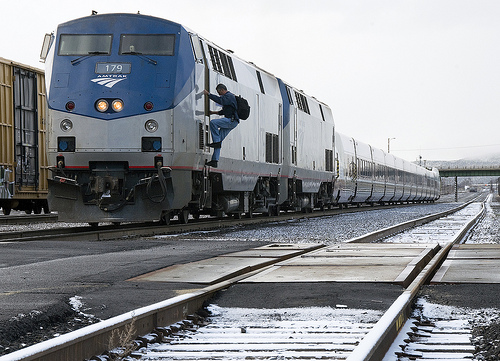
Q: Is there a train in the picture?
A: Yes, there is a train.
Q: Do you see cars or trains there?
A: Yes, there is a train.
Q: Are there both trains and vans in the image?
A: No, there is a train but no vans.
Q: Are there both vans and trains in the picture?
A: No, there is a train but no vans.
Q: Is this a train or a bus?
A: This is a train.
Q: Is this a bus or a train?
A: This is a train.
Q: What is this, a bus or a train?
A: This is a train.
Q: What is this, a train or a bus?
A: This is a train.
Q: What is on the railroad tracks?
A: The train is on the railroad tracks.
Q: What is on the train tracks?
A: The train is on the railroad tracks.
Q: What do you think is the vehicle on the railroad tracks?
A: The vehicle is a train.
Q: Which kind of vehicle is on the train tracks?
A: The vehicle is a train.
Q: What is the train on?
A: The train is on the train tracks.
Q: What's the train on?
A: The train is on the train tracks.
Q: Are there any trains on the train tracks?
A: Yes, there is a train on the train tracks.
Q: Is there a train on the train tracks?
A: Yes, there is a train on the train tracks.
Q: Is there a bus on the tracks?
A: No, there is a train on the tracks.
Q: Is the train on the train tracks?
A: Yes, the train is on the train tracks.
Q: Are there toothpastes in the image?
A: No, there are no toothpastes.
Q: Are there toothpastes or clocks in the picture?
A: No, there are no toothpastes or clocks.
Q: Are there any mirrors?
A: Yes, there is a mirror.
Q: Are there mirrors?
A: Yes, there is a mirror.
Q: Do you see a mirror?
A: Yes, there is a mirror.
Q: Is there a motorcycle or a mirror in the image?
A: Yes, there is a mirror.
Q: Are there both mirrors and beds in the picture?
A: No, there is a mirror but no beds.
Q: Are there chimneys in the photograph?
A: No, there are no chimneys.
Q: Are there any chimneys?
A: No, there are no chimneys.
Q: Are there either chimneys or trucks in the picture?
A: No, there are no chimneys or trucks.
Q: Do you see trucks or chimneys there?
A: No, there are no chimneys or trucks.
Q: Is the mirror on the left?
A: Yes, the mirror is on the left of the image.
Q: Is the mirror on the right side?
A: No, the mirror is on the left of the image.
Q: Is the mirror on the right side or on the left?
A: The mirror is on the left of the image.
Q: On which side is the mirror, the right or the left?
A: The mirror is on the left of the image.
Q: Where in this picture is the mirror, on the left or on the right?
A: The mirror is on the left of the image.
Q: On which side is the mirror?
A: The mirror is on the left of the image.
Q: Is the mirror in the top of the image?
A: Yes, the mirror is in the top of the image.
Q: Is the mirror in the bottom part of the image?
A: No, the mirror is in the top of the image.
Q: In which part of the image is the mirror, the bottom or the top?
A: The mirror is in the top of the image.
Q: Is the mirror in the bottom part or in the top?
A: The mirror is in the top of the image.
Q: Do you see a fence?
A: No, there are no fences.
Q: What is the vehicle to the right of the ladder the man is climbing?
A: The vehicle is a train car.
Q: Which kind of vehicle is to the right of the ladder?
A: The vehicle is a train car.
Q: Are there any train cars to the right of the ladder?
A: Yes, there is a train car to the right of the ladder.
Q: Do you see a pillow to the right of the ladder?
A: No, there is a train car to the right of the ladder.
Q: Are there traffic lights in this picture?
A: No, there are no traffic lights.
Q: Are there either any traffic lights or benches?
A: No, there are no traffic lights or benches.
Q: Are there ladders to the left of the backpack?
A: Yes, there is a ladder to the left of the backpack.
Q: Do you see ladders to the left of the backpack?
A: Yes, there is a ladder to the left of the backpack.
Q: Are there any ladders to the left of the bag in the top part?
A: Yes, there is a ladder to the left of the backpack.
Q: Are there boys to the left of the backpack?
A: No, there is a ladder to the left of the backpack.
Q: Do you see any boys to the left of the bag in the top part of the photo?
A: No, there is a ladder to the left of the backpack.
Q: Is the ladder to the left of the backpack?
A: Yes, the ladder is to the left of the backpack.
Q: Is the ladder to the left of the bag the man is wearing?
A: Yes, the ladder is to the left of the backpack.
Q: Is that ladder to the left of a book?
A: No, the ladder is to the left of the backpack.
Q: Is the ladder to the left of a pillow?
A: No, the ladder is to the left of the train car.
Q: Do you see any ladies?
A: No, there are no ladies.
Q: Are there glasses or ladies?
A: No, there are no ladies or glasses.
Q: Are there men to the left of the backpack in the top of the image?
A: Yes, there is a man to the left of the backpack.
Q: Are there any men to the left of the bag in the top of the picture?
A: Yes, there is a man to the left of the backpack.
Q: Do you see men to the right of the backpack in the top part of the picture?
A: No, the man is to the left of the backpack.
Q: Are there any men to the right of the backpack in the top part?
A: No, the man is to the left of the backpack.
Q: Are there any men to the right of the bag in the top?
A: No, the man is to the left of the backpack.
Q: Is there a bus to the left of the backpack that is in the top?
A: No, there is a man to the left of the backpack.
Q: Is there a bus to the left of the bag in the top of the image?
A: No, there is a man to the left of the backpack.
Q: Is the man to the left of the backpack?
A: Yes, the man is to the left of the backpack.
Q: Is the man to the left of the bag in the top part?
A: Yes, the man is to the left of the backpack.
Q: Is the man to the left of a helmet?
A: No, the man is to the left of the backpack.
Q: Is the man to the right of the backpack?
A: No, the man is to the left of the backpack.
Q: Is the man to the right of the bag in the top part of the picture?
A: No, the man is to the left of the backpack.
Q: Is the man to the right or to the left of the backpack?
A: The man is to the left of the backpack.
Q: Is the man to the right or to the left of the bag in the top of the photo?
A: The man is to the left of the backpack.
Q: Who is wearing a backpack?
A: The man is wearing a backpack.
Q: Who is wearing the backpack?
A: The man is wearing a backpack.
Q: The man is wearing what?
A: The man is wearing a backpack.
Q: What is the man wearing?
A: The man is wearing a backpack.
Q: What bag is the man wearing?
A: The man is wearing a backpack.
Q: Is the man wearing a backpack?
A: Yes, the man is wearing a backpack.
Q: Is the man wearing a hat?
A: No, the man is wearing a backpack.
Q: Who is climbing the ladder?
A: The man is climbing the ladder.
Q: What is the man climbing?
A: The man is climbing the ladder.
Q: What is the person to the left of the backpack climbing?
A: The man is climbing the ladder.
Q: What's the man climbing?
A: The man is climbing the ladder.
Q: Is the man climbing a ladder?
A: Yes, the man is climbing a ladder.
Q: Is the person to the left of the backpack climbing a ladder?
A: Yes, the man is climbing a ladder.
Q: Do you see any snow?
A: Yes, there is snow.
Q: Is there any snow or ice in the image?
A: Yes, there is snow.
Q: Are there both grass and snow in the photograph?
A: No, there is snow but no grass.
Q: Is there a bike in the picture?
A: No, there are no bikes.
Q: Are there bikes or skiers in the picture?
A: No, there are no bikes or skiers.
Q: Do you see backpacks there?
A: Yes, there is a backpack.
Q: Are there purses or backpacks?
A: Yes, there is a backpack.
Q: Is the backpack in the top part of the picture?
A: Yes, the backpack is in the top of the image.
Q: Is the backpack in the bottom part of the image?
A: No, the backpack is in the top of the image.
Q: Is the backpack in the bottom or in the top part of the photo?
A: The backpack is in the top of the image.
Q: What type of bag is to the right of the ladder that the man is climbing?
A: The bag is a backpack.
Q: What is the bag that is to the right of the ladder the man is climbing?
A: The bag is a backpack.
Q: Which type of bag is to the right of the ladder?
A: The bag is a backpack.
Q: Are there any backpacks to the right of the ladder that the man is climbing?
A: Yes, there is a backpack to the right of the ladder.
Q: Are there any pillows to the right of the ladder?
A: No, there is a backpack to the right of the ladder.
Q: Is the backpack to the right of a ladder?
A: Yes, the backpack is to the right of a ladder.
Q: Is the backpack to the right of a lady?
A: No, the backpack is to the right of a ladder.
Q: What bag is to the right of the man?
A: The bag is a backpack.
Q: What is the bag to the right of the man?
A: The bag is a backpack.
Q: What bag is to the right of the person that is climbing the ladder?
A: The bag is a backpack.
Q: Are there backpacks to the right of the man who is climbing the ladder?
A: Yes, there is a backpack to the right of the man.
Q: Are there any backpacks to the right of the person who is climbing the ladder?
A: Yes, there is a backpack to the right of the man.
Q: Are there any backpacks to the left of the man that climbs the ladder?
A: No, the backpack is to the right of the man.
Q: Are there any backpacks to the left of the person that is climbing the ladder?
A: No, the backpack is to the right of the man.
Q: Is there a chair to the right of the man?
A: No, there is a backpack to the right of the man.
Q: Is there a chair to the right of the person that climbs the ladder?
A: No, there is a backpack to the right of the man.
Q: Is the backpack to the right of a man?
A: Yes, the backpack is to the right of a man.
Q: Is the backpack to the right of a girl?
A: No, the backpack is to the right of a man.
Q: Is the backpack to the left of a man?
A: No, the backpack is to the right of a man.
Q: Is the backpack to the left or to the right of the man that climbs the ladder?
A: The backpack is to the right of the man.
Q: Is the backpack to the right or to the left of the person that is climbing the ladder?
A: The backpack is to the right of the man.